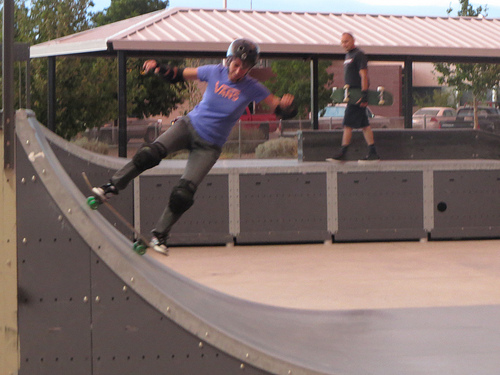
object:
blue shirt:
[187, 62, 269, 145]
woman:
[87, 39, 296, 257]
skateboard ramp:
[14, 107, 498, 371]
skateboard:
[330, 84, 394, 109]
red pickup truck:
[233, 107, 284, 145]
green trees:
[1, 1, 499, 130]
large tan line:
[325, 169, 339, 238]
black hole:
[436, 201, 446, 212]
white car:
[406, 103, 456, 132]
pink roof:
[31, 7, 497, 59]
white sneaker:
[149, 226, 168, 249]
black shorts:
[343, 96, 369, 127]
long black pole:
[114, 48, 128, 155]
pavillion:
[33, 10, 500, 164]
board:
[74, 163, 187, 264]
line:
[230, 165, 244, 239]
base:
[199, 172, 486, 240]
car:
[417, 91, 451, 131]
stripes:
[247, 10, 339, 39]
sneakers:
[82, 175, 179, 265]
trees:
[59, 67, 103, 128]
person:
[98, 14, 288, 258]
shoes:
[93, 178, 189, 268]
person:
[317, 25, 395, 162]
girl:
[153, 25, 278, 286]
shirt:
[194, 56, 249, 161]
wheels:
[78, 185, 172, 275]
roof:
[29, 7, 486, 59]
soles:
[150, 242, 167, 255]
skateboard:
[77, 171, 155, 252]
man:
[326, 31, 390, 160]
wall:
[45, 141, 485, 238]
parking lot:
[94, 100, 475, 145]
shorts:
[340, 100, 370, 127]